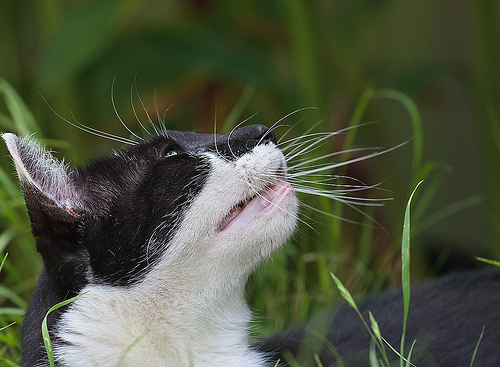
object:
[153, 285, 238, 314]
cat fur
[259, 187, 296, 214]
lips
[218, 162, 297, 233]
mouth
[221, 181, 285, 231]
gums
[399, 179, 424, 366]
blade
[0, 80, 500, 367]
grass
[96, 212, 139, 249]
black fur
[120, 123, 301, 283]
face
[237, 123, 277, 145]
cat nose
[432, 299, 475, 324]
fur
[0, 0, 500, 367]
background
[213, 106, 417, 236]
whiskers cat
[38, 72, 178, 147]
long hairs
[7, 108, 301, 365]
cat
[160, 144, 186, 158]
eye